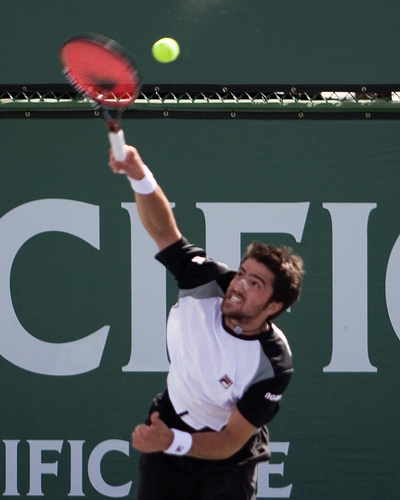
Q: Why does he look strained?
A: From effort.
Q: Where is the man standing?
A: On a court.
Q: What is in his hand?
A: Tennis racket.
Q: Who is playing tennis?
A: The man.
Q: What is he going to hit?
A: The ball.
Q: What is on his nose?
A: A bandage.